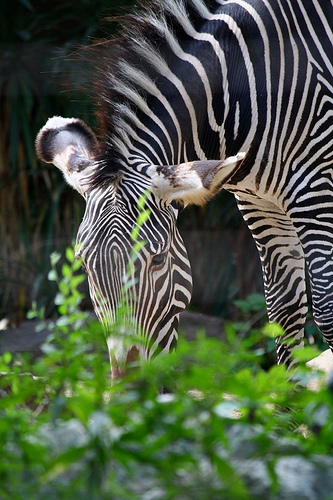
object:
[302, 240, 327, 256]
black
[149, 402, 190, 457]
leaves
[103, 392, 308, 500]
branches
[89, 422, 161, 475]
leaves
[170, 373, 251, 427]
leaves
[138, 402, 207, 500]
close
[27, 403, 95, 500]
blurry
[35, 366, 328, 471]
plants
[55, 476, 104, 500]
green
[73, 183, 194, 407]
head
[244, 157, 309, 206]
zebra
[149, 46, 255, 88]
zebra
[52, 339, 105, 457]
these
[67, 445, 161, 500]
branch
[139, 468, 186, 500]
these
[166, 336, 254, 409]
these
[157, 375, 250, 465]
branch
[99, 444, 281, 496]
these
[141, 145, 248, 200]
ear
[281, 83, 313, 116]
zebra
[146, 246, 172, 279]
eye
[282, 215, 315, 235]
zebra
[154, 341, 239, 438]
leaves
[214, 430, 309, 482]
tree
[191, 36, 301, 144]
zebra fur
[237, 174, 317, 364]
zebra legs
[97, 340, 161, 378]
zebra muzzle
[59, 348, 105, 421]
green plants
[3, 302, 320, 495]
field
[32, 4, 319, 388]
striped mammal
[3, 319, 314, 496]
yard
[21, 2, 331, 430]
zebra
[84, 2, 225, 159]
mane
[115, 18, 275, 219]
neck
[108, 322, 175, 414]
muzzle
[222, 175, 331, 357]
front legs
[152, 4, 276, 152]
stripes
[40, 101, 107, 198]
ear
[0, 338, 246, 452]
leaves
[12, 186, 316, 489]
plant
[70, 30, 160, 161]
hair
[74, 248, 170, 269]
eyes